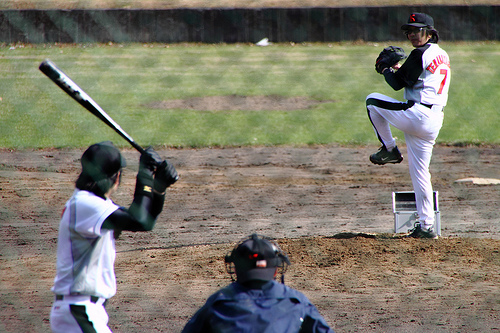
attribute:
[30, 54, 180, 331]
person gloved — black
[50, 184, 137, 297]
shirt — white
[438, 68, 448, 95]
seven — red, number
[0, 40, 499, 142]
grass — green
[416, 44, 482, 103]
shirt — white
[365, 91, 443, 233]
pants — white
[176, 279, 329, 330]
shirt — blue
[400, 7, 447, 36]
hat — black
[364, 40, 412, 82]
glove — black